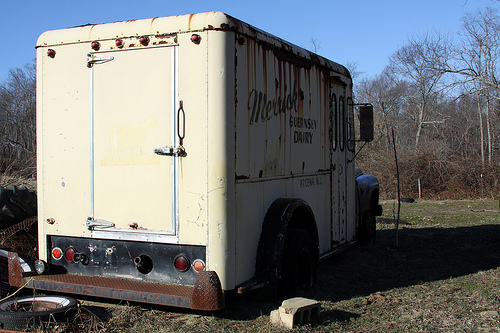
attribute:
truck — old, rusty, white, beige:
[5, 6, 406, 305]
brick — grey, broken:
[258, 290, 327, 331]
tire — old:
[3, 295, 74, 328]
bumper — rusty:
[0, 263, 228, 312]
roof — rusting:
[45, 6, 351, 61]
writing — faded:
[244, 56, 326, 170]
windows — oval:
[330, 90, 352, 148]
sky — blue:
[290, 4, 401, 45]